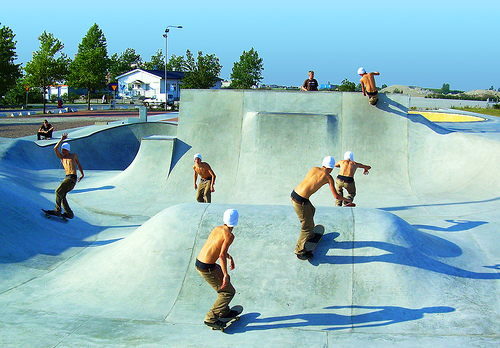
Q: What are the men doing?
A: Skateboarding.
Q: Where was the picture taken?
A: In a skateboard park.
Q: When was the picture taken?
A: During daytime.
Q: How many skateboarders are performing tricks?
A: Six.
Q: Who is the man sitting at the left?
A: A spectator.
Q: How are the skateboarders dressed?
A: In khaki pants and white hats.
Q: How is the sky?
A: Clear.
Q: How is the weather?
A: Warm and sunny.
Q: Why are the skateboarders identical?
A: They are the image of the same person in different positions.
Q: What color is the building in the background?
A: White.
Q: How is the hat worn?
A: Back to front.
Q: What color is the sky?
A: Blue.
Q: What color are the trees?
A: Green.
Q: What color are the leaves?
A: Green.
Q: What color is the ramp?
A: Gray.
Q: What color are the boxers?
A: Black.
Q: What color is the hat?
A: White.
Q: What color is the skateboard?
A: Black.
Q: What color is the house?
A: White.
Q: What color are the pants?
A: Brown.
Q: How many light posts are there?
A: One.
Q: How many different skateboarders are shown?
A: 1.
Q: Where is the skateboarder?
A: Skatepark.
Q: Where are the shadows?
A: On concrete.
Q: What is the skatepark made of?
A: Concrete.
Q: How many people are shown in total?
A: 3.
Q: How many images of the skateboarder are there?
A: 6.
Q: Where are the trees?
A: Background.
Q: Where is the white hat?
A: On skateboarder.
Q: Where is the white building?
A: Near trees.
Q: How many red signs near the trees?
A: 2.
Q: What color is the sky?
A: Blue.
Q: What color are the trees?
A: Green.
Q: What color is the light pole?
A: Gray.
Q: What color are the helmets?
A: White.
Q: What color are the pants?
A: Brown.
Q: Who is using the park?
A: At least 8.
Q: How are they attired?
A: Similarly.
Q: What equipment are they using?
A: Skateboards.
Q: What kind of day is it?
A: Warm clear and bright.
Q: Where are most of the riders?
A: In the middle.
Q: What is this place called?
A: A skateboard park.